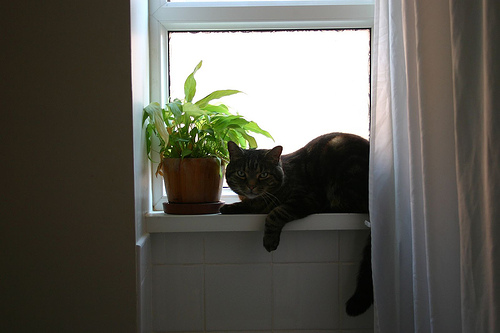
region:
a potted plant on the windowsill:
[131, 67, 264, 224]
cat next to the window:
[216, 115, 396, 248]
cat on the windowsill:
[214, 124, 402, 249]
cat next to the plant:
[144, 70, 415, 246]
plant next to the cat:
[143, 65, 413, 251]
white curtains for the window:
[376, 4, 496, 331]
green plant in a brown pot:
[135, 60, 270, 217]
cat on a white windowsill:
[219, 120, 390, 251]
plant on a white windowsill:
[138, 55, 265, 235]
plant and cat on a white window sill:
[143, 62, 400, 249]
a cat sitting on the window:
[220, 133, 372, 315]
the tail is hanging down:
[346, 243, 370, 318]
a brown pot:
[162, 156, 221, 213]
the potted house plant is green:
[146, 60, 266, 214]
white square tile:
[201, 263, 271, 329]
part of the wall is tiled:
[137, 231, 374, 331]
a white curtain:
[370, 7, 497, 332]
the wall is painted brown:
[3, 0, 138, 331]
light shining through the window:
[168, 30, 371, 148]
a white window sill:
[144, 211, 369, 231]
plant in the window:
[164, 85, 230, 212]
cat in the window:
[233, 121, 380, 243]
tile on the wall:
[208, 232, 270, 267]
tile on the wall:
[156, 265, 205, 324]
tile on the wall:
[210, 268, 269, 328]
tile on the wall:
[266, 261, 333, 325]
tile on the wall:
[331, 269, 365, 325]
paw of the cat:
[260, 228, 292, 249]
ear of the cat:
[270, 144, 286, 166]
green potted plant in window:
[172, 86, 240, 141]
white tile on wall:
[223, 269, 273, 331]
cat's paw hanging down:
[257, 207, 303, 264]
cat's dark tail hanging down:
[347, 224, 395, 309]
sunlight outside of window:
[256, 29, 338, 104]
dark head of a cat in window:
[221, 137, 281, 204]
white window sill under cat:
[156, 187, 326, 242]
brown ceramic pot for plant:
[164, 150, 231, 220]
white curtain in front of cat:
[393, 67, 498, 287]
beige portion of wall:
[10, 81, 91, 200]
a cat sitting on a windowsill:
[145, 38, 400, 258]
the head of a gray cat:
[202, 129, 299, 213]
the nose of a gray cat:
[240, 181, 258, 191]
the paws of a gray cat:
[214, 191, 295, 253]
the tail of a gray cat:
[311, 249, 379, 323]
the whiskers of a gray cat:
[254, 182, 289, 200]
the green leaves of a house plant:
[145, 101, 255, 159]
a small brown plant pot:
[160, 155, 217, 217]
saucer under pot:
[162, 154, 224, 215]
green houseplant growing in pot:
[139, 58, 277, 211]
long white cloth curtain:
[366, 2, 499, 332]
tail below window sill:
[343, 223, 375, 307]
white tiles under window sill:
[145, 230, 373, 331]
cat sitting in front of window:
[216, 131, 375, 313]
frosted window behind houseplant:
[151, 1, 376, 210]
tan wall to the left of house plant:
[0, 0, 135, 331]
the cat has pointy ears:
[226, 140, 282, 163]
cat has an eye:
[237, 166, 249, 176]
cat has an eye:
[260, 171, 267, 177]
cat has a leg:
[222, 200, 266, 212]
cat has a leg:
[260, 201, 312, 251]